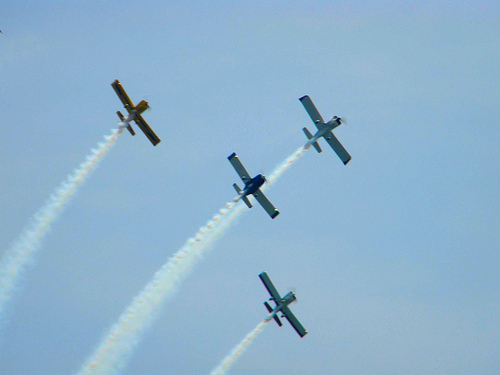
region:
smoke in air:
[0, 123, 306, 374]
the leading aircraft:
[298, 86, 351, 165]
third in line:
[108, 76, 307, 346]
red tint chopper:
[110, 75, 162, 146]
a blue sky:
[3, 0, 497, 372]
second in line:
[228, 147, 279, 224]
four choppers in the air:
[107, 74, 352, 339]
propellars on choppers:
[136, 89, 348, 305]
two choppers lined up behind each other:
[224, 92, 354, 220]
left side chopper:
[111, 72, 162, 146]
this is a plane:
[259, 265, 323, 352]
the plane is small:
[237, 267, 249, 277]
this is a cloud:
[126, 261, 200, 311]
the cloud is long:
[160, 272, 185, 301]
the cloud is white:
[157, 253, 207, 308]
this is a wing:
[252, 200, 283, 224]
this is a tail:
[224, 188, 264, 220]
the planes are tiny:
[223, 158, 325, 240]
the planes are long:
[297, 261, 317, 342]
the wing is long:
[220, 235, 295, 317]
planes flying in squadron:
[110, 76, 353, 338]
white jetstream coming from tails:
[1, 122, 308, 373]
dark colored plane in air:
[111, 78, 161, 145]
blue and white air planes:
[227, 94, 350, 336]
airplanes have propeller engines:
[108, 77, 350, 337]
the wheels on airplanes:
[121, 101, 331, 319]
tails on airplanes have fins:
[114, 106, 321, 328]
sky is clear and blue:
[1, 2, 498, 374]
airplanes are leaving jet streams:
[1, 72, 349, 373]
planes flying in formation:
[108, 72, 357, 344]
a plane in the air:
[93, 48, 178, 165]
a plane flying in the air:
[196, 130, 311, 234]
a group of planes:
[52, 42, 407, 362]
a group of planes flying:
[55, 19, 405, 372]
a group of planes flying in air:
[88, 56, 486, 368]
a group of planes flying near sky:
[78, 68, 375, 368]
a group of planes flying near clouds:
[73, 38, 445, 351]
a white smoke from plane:
[21, 166, 95, 235]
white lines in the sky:
[100, 252, 230, 363]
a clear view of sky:
[22, 19, 473, 351]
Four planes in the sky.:
[110, 78, 355, 339]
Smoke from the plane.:
[219, 202, 241, 222]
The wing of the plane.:
[281, 306, 306, 336]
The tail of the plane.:
[233, 184, 253, 210]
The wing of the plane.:
[298, 93, 324, 128]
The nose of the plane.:
[136, 99, 151, 112]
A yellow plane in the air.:
[108, 79, 162, 145]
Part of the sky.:
[363, 252, 415, 302]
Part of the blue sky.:
[205, 59, 260, 109]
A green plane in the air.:
[301, 93, 352, 166]